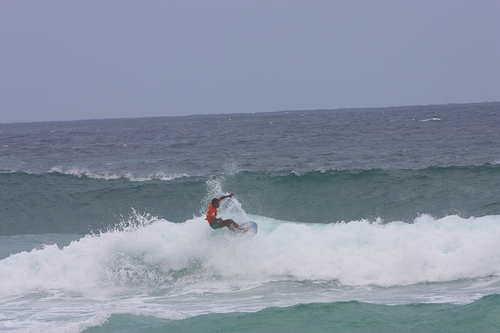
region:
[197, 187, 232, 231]
male surfer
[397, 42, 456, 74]
white clouds in blue sky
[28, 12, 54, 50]
white clouds in blue sky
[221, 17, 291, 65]
white clouds in blue sky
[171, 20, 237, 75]
white clouds in blue sky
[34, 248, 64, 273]
white wave in water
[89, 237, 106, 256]
white wave in water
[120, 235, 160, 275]
white wave in water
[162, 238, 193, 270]
white wave in water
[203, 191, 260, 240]
person on a surfboard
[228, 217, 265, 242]
board on the person's feet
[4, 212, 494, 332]
medium size wave in the ocean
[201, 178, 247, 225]
back splash from the surfboard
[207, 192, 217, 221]
the man is wearing a red shirt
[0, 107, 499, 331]
area of ocean being used for surfing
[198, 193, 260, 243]
the man is riding a wave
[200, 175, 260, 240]
the man is balancing on a surfboard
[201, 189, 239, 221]
the man's arms are up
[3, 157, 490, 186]
a wave beginning to form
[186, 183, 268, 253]
A man surfing a wave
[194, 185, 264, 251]
A man surfing a wave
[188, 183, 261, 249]
A man surfing a wave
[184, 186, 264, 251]
A man surfing a wave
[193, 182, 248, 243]
surfer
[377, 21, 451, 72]
white clouds in blue sky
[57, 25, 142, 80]
white clouds in blue sky